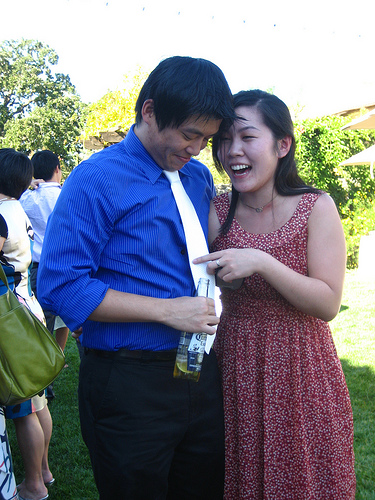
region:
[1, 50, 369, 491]
People having a fun time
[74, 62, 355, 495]
A man and woman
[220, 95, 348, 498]
Woman is laughing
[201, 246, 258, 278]
hand is holding his tie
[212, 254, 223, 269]
She is wearing a ring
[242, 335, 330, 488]
her dress is red with dots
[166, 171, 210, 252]
His tie is white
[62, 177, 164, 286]
His shirt is blue with stripes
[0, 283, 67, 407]
The purse is green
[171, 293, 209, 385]
He is holding a beer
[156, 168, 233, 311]
A white dress tie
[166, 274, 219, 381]
An almost empty beer bottle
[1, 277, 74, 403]
An big ugly green bag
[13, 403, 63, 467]
A Woman's calf muscles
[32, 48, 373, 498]
A man and woman laughing together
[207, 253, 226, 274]
A woman's silver ring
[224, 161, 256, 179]
A woman's white teeth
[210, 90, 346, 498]
A woman in a red dress laughing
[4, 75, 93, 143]
Green leafs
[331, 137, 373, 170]
Part of a roof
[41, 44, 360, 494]
couple standing together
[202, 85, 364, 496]
girl with pink dress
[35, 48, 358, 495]
asian people staniding together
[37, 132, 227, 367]
blue t-shirt of man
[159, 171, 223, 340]
gray tie of man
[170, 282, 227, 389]
beer bottle on hand of man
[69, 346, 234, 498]
black pants of amn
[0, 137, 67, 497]
two people are standing in the left sde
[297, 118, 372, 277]
green bushes in the left side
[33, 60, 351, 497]
two people laughin together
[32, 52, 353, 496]
Two people are standing next to each other.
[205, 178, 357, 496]
The woman is wearing a red dress with white dots.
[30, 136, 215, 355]
The man is wearing a blue shirt with pin stripes.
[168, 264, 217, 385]
The man is holding a beer.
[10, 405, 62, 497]
The woman's calves are bare.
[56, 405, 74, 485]
The grass is green.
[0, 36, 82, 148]
A tree is in the background.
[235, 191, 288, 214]
The woman is wearing a necklace.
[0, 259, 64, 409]
The bag is green.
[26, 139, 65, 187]
A person with black hair.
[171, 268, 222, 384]
The bottle is clear with yellow liquid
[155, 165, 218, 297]
The tie is white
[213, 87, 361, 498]
The woman is wearing a dress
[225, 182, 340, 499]
The dress is red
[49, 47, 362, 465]
Woman standing with a man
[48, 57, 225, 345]
Man wearing a blue shirt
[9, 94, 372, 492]
People on the grass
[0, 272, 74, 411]
The bag is green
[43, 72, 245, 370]
The man is holding a beer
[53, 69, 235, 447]
The man is wearing black pants